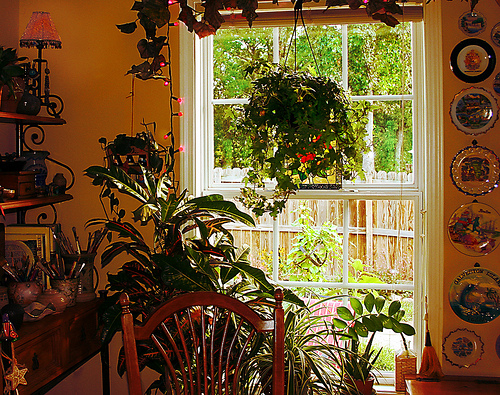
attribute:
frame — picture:
[5, 222, 56, 261]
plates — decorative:
[451, 8, 498, 360]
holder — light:
[19, 11, 70, 121]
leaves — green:
[327, 295, 417, 341]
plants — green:
[104, 57, 394, 392]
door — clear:
[220, 32, 430, 363]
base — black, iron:
[27, 40, 64, 118]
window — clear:
[212, 32, 275, 108]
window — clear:
[282, 23, 352, 113]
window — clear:
[351, 17, 428, 111]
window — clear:
[336, 93, 422, 184]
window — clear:
[208, 102, 282, 182]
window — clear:
[349, 194, 451, 289]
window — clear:
[278, 203, 357, 290]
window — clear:
[203, 198, 278, 295]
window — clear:
[346, 286, 426, 363]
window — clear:
[288, 286, 340, 353]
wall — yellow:
[80, 44, 120, 94]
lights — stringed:
[158, 39, 196, 179]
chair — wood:
[116, 281, 287, 391]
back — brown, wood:
[114, 292, 299, 393]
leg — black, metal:
[100, 342, 116, 392]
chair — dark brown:
[99, 282, 307, 392]